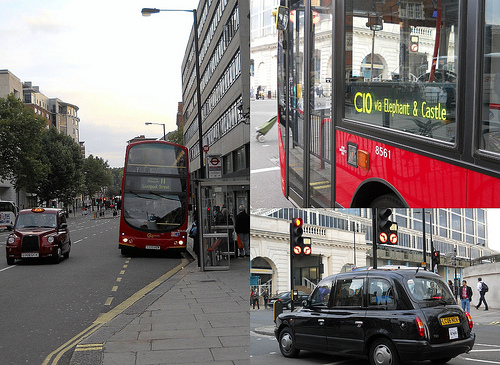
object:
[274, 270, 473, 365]
car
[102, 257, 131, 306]
lines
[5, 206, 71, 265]
taxi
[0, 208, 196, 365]
city street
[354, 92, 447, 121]
sign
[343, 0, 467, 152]
window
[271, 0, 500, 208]
bus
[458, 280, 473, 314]
person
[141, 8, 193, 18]
street light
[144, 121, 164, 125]
street light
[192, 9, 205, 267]
pole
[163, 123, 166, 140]
pole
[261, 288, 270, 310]
person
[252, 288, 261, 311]
person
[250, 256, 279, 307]
archway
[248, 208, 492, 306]
building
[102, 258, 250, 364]
pattern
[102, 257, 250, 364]
sidewalk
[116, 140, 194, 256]
bus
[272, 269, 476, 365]
cab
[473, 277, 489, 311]
man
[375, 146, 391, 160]
number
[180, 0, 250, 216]
building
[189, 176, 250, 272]
waiting station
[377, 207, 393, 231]
traffic light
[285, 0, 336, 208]
door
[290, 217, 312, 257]
caution light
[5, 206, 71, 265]
cab